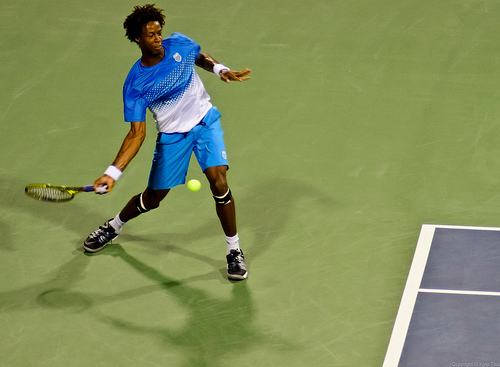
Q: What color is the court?
A: Green.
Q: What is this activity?
A: Tennis.